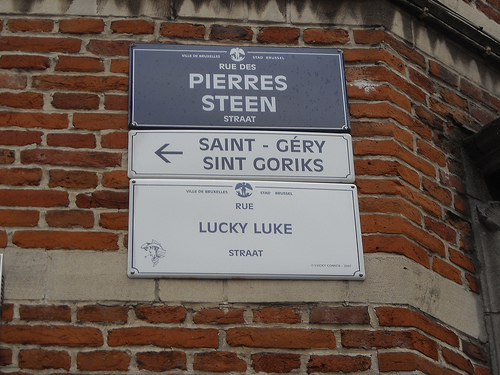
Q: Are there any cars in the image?
A: No, there are no cars.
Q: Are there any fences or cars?
A: No, there are no cars or fences.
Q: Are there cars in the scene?
A: No, there are no cars.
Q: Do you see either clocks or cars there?
A: No, there are no cars or clocks.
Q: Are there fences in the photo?
A: No, there are no fences.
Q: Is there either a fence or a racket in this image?
A: No, there are no fences or rackets.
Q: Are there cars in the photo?
A: No, there are no cars.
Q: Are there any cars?
A: No, there are no cars.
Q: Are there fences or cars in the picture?
A: No, there are no cars or fences.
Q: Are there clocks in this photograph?
A: No, there are no clocks.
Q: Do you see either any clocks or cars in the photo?
A: No, there are no clocks or cars.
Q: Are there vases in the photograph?
A: No, there are no vases.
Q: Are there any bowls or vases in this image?
A: No, there are no vases or bowls.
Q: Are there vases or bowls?
A: No, there are no vases or bowls.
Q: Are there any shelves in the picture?
A: No, there are no shelves.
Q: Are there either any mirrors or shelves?
A: No, there are no shelves or mirrors.